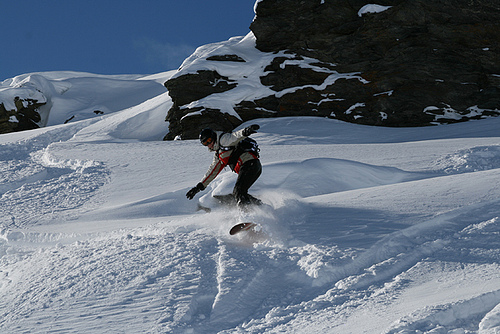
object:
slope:
[0, 88, 500, 333]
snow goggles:
[201, 136, 213, 144]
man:
[183, 124, 263, 219]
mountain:
[1, 1, 498, 332]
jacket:
[200, 128, 261, 188]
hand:
[184, 185, 200, 200]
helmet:
[196, 129, 218, 148]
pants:
[233, 158, 262, 208]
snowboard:
[228, 222, 257, 236]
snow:
[1, 32, 500, 333]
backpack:
[240, 136, 262, 153]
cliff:
[163, 0, 500, 140]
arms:
[195, 151, 230, 191]